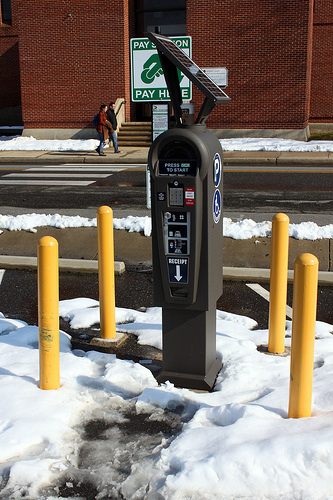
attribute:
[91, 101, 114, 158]
woman — walking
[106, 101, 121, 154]
man — walking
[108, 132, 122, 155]
jeans — blue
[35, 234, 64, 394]
pole — yellow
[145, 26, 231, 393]
parking meter — short, grey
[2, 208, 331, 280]
sidewalk — snowy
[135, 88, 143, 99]
letter — white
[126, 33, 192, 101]
sign — green, white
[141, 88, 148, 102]
letter — white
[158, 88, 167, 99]
letter — white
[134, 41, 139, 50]
letter — white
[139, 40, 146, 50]
letter — white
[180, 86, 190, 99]
letter — white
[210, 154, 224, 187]
sign — blue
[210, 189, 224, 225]
sign — blue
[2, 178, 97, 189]
line — white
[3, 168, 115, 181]
line — white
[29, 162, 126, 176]
line — white